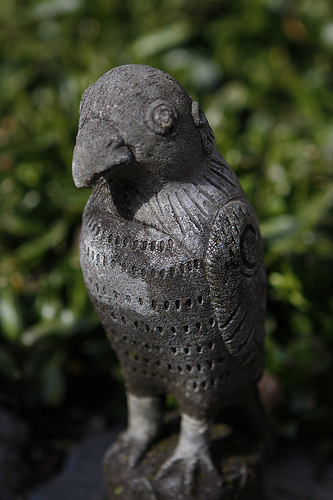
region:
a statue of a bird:
[63, 42, 303, 490]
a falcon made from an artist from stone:
[0, 25, 308, 485]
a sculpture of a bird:
[9, 43, 244, 472]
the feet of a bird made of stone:
[69, 377, 274, 497]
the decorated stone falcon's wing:
[201, 200, 297, 403]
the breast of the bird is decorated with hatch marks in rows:
[70, 221, 222, 411]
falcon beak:
[34, 96, 144, 221]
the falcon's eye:
[129, 94, 190, 153]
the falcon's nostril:
[95, 130, 119, 154]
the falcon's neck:
[137, 148, 239, 190]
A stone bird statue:
[27, 50, 281, 454]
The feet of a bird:
[78, 378, 243, 485]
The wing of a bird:
[180, 184, 276, 388]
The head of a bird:
[50, 53, 214, 222]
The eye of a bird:
[150, 90, 183, 153]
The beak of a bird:
[53, 117, 130, 215]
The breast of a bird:
[53, 212, 228, 367]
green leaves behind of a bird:
[26, 27, 278, 251]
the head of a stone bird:
[47, 49, 220, 224]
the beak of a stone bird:
[43, 111, 141, 218]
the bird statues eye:
[141, 102, 186, 142]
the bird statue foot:
[181, 418, 217, 486]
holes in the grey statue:
[160, 306, 196, 369]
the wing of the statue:
[216, 214, 270, 328]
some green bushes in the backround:
[12, 153, 41, 238]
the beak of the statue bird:
[70, 127, 114, 175]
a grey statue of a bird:
[73, 75, 279, 485]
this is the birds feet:
[112, 411, 220, 472]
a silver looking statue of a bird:
[73, 8, 247, 486]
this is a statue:
[76, 72, 268, 479]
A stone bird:
[29, 72, 280, 477]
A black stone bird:
[42, 66, 280, 483]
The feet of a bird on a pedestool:
[88, 395, 248, 495]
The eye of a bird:
[128, 85, 187, 148]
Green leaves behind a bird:
[19, 53, 202, 282]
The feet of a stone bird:
[86, 389, 234, 480]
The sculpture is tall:
[61, 54, 265, 468]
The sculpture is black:
[57, 56, 263, 425]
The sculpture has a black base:
[89, 392, 277, 490]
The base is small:
[80, 397, 260, 495]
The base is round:
[91, 414, 261, 497]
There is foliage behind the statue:
[25, 7, 308, 277]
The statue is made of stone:
[63, 55, 274, 474]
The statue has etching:
[75, 208, 231, 424]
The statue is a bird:
[62, 69, 270, 457]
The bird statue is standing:
[61, 50, 260, 385]